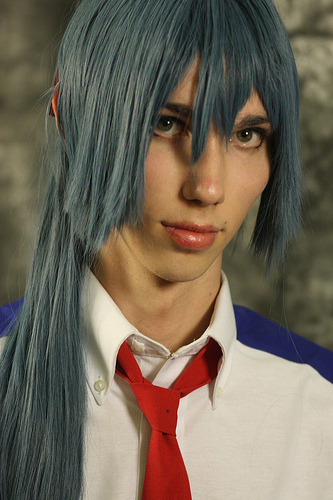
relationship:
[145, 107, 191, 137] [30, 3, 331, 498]
eye on person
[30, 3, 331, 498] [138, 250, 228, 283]
person has chin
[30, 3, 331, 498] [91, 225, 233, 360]
person has neck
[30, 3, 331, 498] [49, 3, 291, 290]
person has head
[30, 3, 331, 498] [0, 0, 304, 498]
person has hair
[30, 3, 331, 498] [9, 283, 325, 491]
person wears costume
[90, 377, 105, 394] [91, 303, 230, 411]
button on collar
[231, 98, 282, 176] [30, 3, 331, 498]
eye of person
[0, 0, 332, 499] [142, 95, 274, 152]
guy with eyeliner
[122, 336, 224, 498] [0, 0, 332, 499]
neck tie on guy